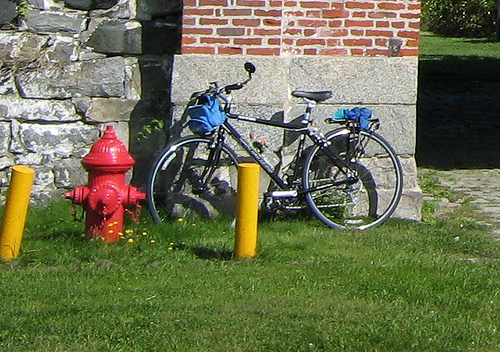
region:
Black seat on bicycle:
[291, 88, 334, 102]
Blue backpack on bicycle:
[185, 93, 226, 132]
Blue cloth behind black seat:
[345, 105, 375, 130]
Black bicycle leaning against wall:
[148, 60, 404, 230]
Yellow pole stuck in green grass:
[235, 161, 260, 256]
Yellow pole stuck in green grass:
[0, 164, 37, 262]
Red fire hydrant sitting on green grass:
[65, 123, 149, 241]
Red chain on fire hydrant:
[67, 201, 86, 223]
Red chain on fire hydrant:
[97, 203, 109, 228]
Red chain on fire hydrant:
[127, 201, 143, 223]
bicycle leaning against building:
[155, 78, 397, 231]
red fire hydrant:
[44, 122, 163, 239]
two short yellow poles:
[2, 158, 283, 263]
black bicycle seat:
[286, 77, 338, 114]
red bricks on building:
[171, 0, 416, 50]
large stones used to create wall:
[15, 14, 149, 186]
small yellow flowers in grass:
[75, 213, 193, 265]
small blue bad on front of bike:
[174, 83, 250, 139]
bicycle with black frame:
[144, 74, 431, 227]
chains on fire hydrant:
[69, 203, 146, 228]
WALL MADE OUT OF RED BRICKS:
[246, 18, 282, 37]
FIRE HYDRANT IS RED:
[86, 132, 118, 232]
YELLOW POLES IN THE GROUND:
[237, 170, 257, 255]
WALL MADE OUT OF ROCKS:
[38, 68, 80, 98]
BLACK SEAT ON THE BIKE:
[293, 90, 327, 97]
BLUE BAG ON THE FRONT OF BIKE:
[191, 100, 215, 131]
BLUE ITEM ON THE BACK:
[332, 108, 364, 122]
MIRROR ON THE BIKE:
[241, 63, 261, 82]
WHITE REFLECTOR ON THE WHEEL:
[166, 153, 176, 165]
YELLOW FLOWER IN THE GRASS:
[167, 244, 178, 251]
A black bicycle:
[151, 48, 398, 235]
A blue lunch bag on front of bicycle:
[171, 80, 232, 131]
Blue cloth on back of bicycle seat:
[329, 103, 384, 128]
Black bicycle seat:
[292, 85, 333, 100]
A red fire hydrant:
[67, 121, 151, 238]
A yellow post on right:
[225, 154, 266, 266]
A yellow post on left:
[0, 158, 41, 268]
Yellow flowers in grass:
[100, 220, 197, 260]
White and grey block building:
[5, 12, 147, 202]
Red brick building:
[176, 5, 399, 55]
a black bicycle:
[146, 63, 401, 232]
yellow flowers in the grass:
[53, 212, 201, 260]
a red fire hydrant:
[63, 124, 145, 244]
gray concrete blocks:
[168, 55, 421, 222]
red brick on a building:
[180, 0, 418, 54]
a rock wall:
[2, 0, 182, 201]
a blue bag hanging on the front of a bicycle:
[145, 61, 405, 228]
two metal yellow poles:
[2, 162, 259, 262]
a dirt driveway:
[419, 79, 499, 230]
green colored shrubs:
[419, 2, 499, 37]